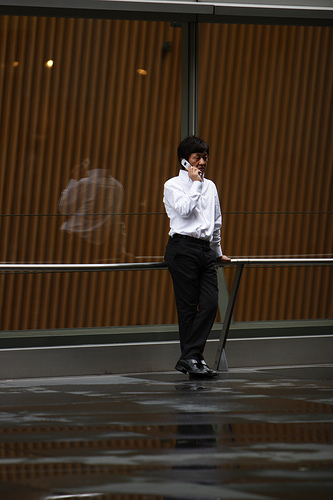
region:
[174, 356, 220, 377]
a pair of men's black dress shoes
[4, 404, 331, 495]
water on a black road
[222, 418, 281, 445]
a puddle of water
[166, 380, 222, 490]
a man's reflection in a puddle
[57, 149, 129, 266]
a man's reflection in a window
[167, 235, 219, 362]
a black pair of dress slacks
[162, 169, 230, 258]
a white dress shirt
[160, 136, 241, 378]
a man talking on a cell phone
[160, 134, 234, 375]
a man leaning on a hand rail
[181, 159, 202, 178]
a white flip phone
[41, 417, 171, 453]
a puddle of water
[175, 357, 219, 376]
shinny black men's shoes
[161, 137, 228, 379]
a guy standing on a road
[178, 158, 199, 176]
a white flip cell phone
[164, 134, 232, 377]
a man leaning on a handrail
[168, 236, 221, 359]
black dress pants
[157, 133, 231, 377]
Man talking on a cellphone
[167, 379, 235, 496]
Reflection of man in the water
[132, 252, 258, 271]
Man leaning and holding onto steel railing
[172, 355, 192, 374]
Big heel on dress shoes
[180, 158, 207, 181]
Old flip style cellphone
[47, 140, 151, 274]
Reflection of man in the glass window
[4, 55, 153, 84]
Reflection of lights in the window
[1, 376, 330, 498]
Puddles on the surface of the walkway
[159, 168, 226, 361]
Wearing black pants and a white shirt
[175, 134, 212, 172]
Man has dark brown hair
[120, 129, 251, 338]
man talking on a cellphone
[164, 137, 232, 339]
a business man on a phone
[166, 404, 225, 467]
the man's reflection in hte water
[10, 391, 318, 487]
water in the area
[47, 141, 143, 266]
the man's reflection in the mirror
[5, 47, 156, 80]
lights in the building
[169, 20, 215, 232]
a window seal on the building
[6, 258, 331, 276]
a rail behind on the building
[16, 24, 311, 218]
a brown wall in the background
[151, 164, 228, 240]
this man is wearing a white shirt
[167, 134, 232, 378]
man talking on cellphone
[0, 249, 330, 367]
railing man is leading on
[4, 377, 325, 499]
water puddling on pavement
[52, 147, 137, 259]
reflection of man on window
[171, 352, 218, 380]
black shoes of man on phone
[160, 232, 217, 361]
black dress pants of man on phone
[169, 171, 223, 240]
white shirt of man on cellphone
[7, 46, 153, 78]
lights reflected on window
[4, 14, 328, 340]
windows behind man on phone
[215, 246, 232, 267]
man's hand holding onto rail